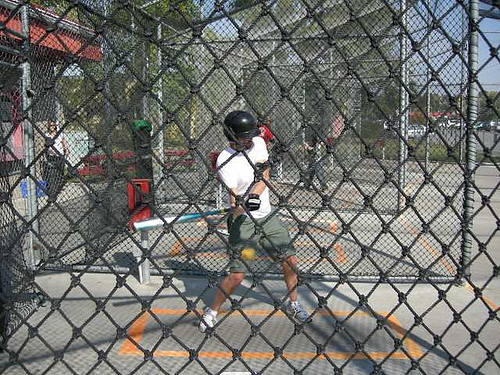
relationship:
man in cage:
[194, 105, 305, 327] [50, 265, 162, 371]